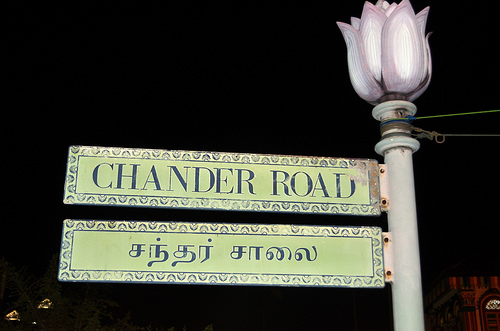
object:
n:
[167, 164, 190, 192]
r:
[269, 168, 292, 198]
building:
[424, 261, 500, 331]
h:
[114, 162, 141, 190]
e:
[210, 166, 237, 193]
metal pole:
[367, 98, 424, 331]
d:
[189, 166, 216, 193]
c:
[93, 161, 117, 189]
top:
[334, 0, 434, 105]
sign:
[54, 218, 385, 288]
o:
[290, 171, 312, 196]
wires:
[417, 109, 498, 143]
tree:
[6, 298, 56, 328]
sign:
[60, 144, 384, 219]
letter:
[232, 165, 259, 198]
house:
[1, 260, 102, 329]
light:
[35, 297, 56, 312]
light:
[4, 307, 22, 321]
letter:
[269, 169, 292, 199]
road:
[269, 165, 362, 204]